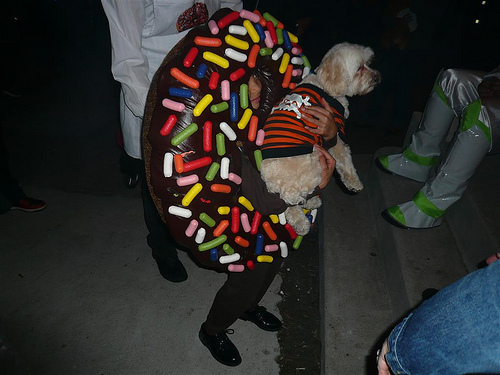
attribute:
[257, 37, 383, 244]
dog — furry, tan, brown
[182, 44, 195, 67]
confection — red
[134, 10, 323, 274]
donut — chocolate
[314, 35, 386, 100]
head — dogs 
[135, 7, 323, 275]
costume — donut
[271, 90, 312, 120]
skull — tan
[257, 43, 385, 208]
dog — tan, furry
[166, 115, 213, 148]
sprinkle — green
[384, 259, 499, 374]
jeans — blue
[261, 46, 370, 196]
fur — tan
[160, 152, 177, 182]
sprinkle — white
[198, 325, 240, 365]
shoe — black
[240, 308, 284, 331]
shoe — black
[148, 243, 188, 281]
shoe — black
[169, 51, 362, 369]
person — child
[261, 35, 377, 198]
dog — furry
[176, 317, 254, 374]
shoe — black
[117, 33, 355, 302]
boy —  young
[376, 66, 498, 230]
person — sitting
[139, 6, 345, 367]
person — child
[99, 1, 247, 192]
person — standing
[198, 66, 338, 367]
lady — light skinned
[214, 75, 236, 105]
sprinkle — pink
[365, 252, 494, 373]
surface — denim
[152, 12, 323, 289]
tube — inflatable 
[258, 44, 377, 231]
dog — tan, furry